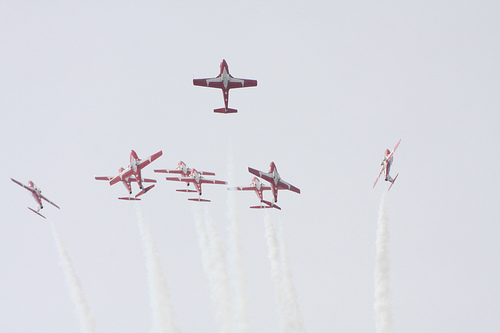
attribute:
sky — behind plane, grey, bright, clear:
[1, 1, 500, 330]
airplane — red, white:
[246, 159, 300, 203]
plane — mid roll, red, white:
[368, 138, 401, 190]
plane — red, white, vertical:
[191, 58, 258, 115]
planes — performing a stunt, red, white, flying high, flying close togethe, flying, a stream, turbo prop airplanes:
[12, 59, 403, 223]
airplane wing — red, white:
[229, 76, 258, 90]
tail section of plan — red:
[214, 90, 238, 114]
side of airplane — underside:
[191, 57, 258, 114]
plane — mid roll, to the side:
[11, 177, 61, 218]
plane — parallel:
[155, 162, 228, 204]